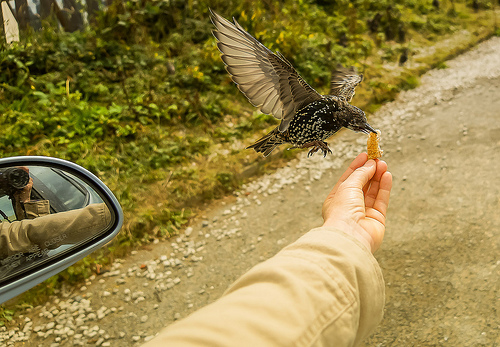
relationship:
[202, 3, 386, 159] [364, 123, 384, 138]
bird has beak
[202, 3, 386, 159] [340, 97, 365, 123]
bird has head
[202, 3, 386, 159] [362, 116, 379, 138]
bird has beak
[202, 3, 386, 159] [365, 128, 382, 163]
bird eats bread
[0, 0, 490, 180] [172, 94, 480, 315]
greenery on road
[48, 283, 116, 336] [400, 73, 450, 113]
pebbles on ground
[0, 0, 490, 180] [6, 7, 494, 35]
greenery on background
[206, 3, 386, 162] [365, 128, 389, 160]
bird takes food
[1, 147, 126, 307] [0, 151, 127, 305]
sideview mirror has mans reflection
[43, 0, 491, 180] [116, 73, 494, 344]
greenery on road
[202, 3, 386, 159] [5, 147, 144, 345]
bird close car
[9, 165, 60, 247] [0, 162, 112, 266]
man has mans reflection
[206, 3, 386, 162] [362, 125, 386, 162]
bird accepts treat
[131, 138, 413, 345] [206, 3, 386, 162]
human feeds bird